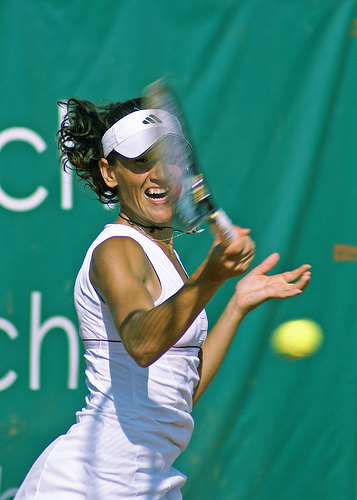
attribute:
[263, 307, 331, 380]
ball — flying, green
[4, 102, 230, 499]
player — sleeveless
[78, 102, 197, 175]
cap — white, adidas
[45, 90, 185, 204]
hair — short, brown, up, black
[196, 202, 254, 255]
handle — white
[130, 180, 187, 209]
mouth — open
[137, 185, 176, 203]
teeth — white, showing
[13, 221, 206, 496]
dress — white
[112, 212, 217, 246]
necklace — black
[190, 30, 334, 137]
wall — blue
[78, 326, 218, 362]
stripe — black, dark, thin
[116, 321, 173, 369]
elbow — bent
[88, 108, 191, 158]
design — black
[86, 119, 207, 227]
player — showing emotion, smiling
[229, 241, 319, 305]
hand — open, up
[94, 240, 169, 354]
arm — muscular, sleeveless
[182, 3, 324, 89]
background — green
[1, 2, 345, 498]
board — green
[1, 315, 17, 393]
letter — white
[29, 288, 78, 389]
letter — white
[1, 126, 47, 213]
letter — white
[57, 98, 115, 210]
letter — white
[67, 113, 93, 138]
curl — dark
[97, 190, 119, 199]
curl — dark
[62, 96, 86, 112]
curl — dark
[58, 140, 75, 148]
curl — dark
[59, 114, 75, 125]
curl — dark